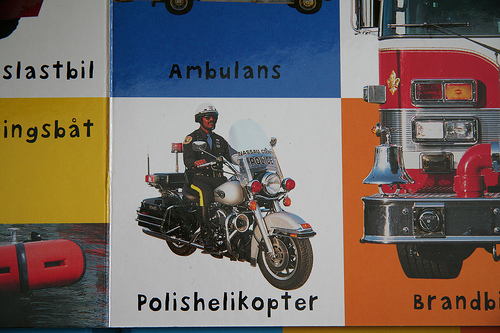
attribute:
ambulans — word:
[167, 59, 283, 81]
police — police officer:
[181, 102, 249, 251]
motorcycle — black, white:
[133, 117, 316, 290]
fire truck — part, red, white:
[349, 0, 498, 280]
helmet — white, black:
[194, 102, 220, 119]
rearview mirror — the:
[190, 137, 217, 161]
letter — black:
[168, 60, 182, 81]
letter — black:
[182, 61, 202, 81]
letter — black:
[204, 59, 217, 83]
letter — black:
[232, 57, 242, 80]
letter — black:
[243, 60, 255, 82]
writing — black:
[2, 116, 96, 142]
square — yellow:
[1, 97, 110, 224]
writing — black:
[133, 285, 321, 318]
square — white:
[110, 96, 343, 329]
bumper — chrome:
[359, 189, 499, 249]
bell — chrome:
[358, 125, 412, 196]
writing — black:
[411, 289, 499, 312]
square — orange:
[341, 99, 498, 328]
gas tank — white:
[212, 178, 243, 209]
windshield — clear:
[227, 117, 271, 171]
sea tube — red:
[2, 226, 86, 303]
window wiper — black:
[382, 22, 499, 55]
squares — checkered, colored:
[0, 0, 498, 327]